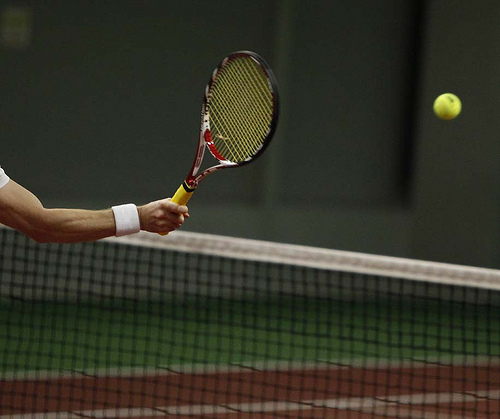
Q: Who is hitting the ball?
A: Tennis player.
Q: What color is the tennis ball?
A: Yellow.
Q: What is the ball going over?
A: A net.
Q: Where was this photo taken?
A: Tennis court.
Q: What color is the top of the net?
A: White.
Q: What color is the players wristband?
A: White.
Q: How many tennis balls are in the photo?
A: One.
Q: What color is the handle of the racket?
A: Yellow.